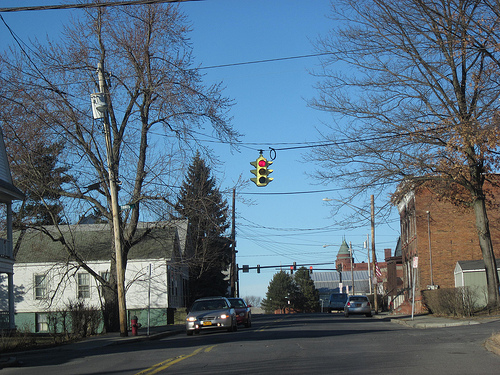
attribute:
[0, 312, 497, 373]
concrete — painted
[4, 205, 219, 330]
house — green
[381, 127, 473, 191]
wall — tall, wooden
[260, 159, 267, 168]
light — red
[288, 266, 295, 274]
traffic light — large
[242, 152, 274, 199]
light — glowing, red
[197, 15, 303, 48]
sky — clear, blue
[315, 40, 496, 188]
leaves — green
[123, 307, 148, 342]
hydrant — green, red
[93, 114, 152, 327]
pole — tall, wooden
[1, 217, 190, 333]
house — white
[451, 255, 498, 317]
shed — small, grey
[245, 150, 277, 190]
light box — hanging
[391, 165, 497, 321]
building — brown, brick, two story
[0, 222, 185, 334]
building — white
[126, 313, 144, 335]
hydrant — red